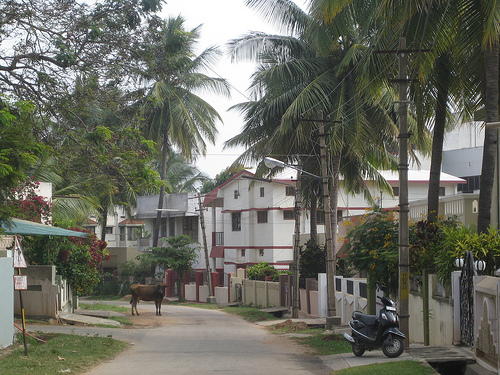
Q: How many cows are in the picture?
A: One.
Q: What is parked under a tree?
A: A motorcycle.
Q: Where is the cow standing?
A: On a street.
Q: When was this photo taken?
A: Daytime.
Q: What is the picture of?
A: A small tropical village.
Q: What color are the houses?
A: White.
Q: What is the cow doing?
A: Standing.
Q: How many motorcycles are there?
A: One.